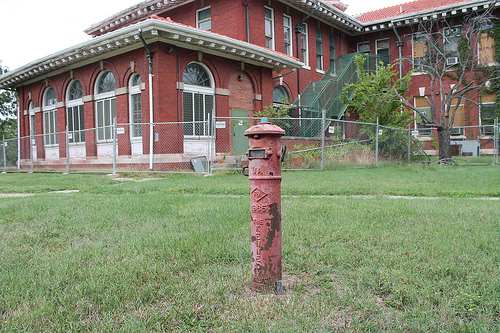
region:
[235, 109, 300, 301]
an old fire hydrant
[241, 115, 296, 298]
fire hydrant is rusty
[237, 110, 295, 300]
fire hydrant is color red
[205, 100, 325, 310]
fire hydrant is on green grass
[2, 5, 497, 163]
building is made of red bricks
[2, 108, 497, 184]
metal fence around the house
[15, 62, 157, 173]
five doors on side the building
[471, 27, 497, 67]
window of house is covered with wood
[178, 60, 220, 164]
door of house is white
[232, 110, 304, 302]
An old water hydrant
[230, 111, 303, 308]
An old water hydrant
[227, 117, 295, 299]
An old water hydrant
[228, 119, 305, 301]
An old water hydrant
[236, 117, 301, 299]
An old water hydrant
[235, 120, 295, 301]
An old water hydrant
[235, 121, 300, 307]
An old water hydrant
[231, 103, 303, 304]
Red bollard sticking out of ground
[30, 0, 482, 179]
Large abandoned brick building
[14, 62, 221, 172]
Large windows with arched tops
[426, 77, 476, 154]
Plywood covering broken windows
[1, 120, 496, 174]
Long chainlink fence around building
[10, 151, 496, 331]
Mowed green grass lawn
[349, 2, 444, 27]
Light red terra cotta roof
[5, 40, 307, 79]
White painted decorative effects on roof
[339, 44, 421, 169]
Green overgrown tall bushes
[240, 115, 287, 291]
A hydrant in the grass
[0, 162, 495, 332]
A grassy area beneath the hydrant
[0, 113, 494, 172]
A fence near the building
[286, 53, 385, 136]
Stairs by the building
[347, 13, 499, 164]
Trees near the fence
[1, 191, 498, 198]
A path in the grass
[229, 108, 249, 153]
A door on the building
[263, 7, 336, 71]
Windows on the building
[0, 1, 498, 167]
A building near the hydrant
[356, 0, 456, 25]
The roof of the building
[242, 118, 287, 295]
red pole in the grass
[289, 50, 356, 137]
green covered staircase along the building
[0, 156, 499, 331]
green grass out front of the building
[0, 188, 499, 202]
gray sidewalk through the grass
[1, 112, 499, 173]
silver metal fence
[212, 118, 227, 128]
white sign on the silver metal fence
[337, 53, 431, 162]
green tree by the building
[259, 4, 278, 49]
rectangular window on the building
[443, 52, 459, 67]
A/C unit in the window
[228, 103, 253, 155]
green door on the building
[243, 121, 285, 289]
a tall red hydrant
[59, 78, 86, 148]
window on a building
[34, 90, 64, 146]
window on a building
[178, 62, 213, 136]
window on a building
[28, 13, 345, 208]
this is a large building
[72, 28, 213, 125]
the building is brick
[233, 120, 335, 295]
the hydrant is red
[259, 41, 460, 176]
the stairs are green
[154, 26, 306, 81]
the gutter is white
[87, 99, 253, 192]
the fence is chain link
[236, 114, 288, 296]
The red hydrant in the field.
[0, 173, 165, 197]
The concrete path in the yard.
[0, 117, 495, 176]
The chainlink fence in front of the building.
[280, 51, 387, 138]
The green stairs on the building.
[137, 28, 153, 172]
The drain on the wall.